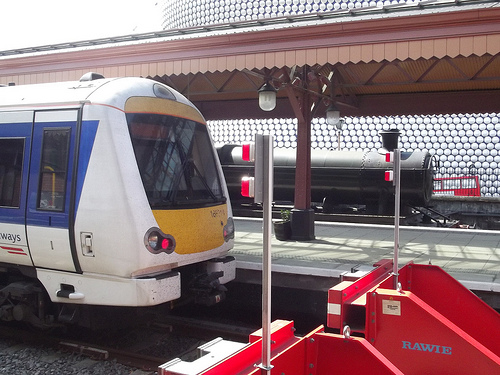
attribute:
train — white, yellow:
[0, 72, 236, 335]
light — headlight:
[146, 228, 161, 255]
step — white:
[55, 289, 85, 300]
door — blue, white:
[25, 107, 82, 273]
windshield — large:
[126, 113, 226, 212]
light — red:
[160, 235, 174, 252]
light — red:
[223, 227, 229, 240]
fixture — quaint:
[258, 71, 278, 110]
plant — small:
[274, 207, 294, 241]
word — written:
[401, 340, 450, 354]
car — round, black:
[217, 141, 440, 223]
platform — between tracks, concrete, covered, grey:
[235, 216, 498, 305]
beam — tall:
[293, 70, 315, 240]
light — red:
[241, 177, 252, 199]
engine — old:
[218, 144, 475, 226]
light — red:
[242, 144, 251, 160]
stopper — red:
[158, 258, 499, 374]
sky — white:
[1, 0, 160, 52]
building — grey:
[156, 1, 430, 31]